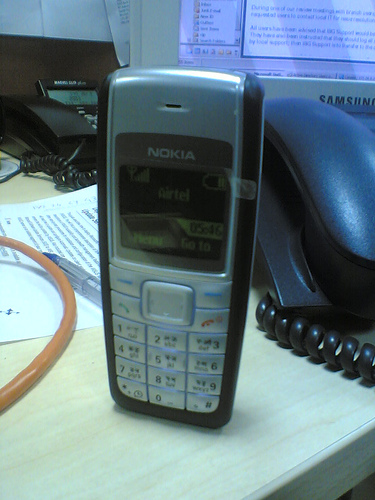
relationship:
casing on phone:
[218, 82, 293, 447] [76, 61, 298, 448]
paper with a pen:
[0, 186, 104, 343] [42, 250, 103, 303]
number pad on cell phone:
[109, 289, 220, 417] [96, 70, 267, 430]